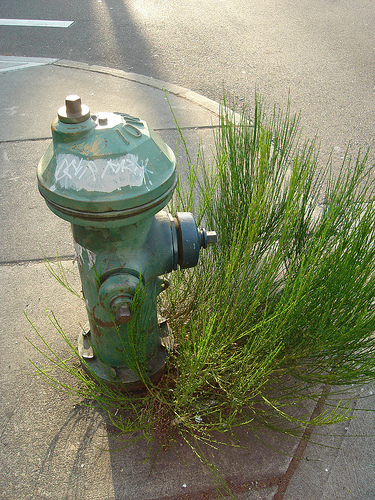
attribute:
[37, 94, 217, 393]
fire hydrant — green, rusted, rusty, metal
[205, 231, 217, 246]
screw — rusty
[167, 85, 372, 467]
grass — tall, green, long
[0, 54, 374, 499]
sidewalk — gray, concrete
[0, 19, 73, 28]
line — white, paint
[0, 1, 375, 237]
street — gray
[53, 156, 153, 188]
graffiti — white